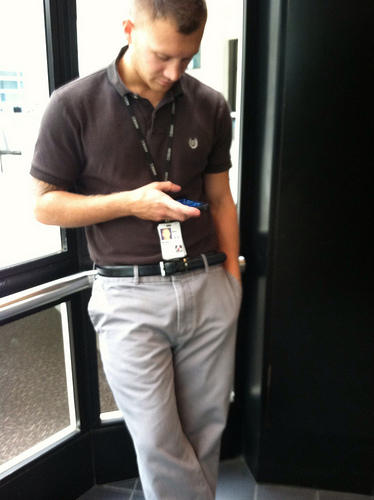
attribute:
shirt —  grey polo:
[26, 43, 233, 266]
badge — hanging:
[123, 95, 187, 259]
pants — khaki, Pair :
[75, 255, 265, 415]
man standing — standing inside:
[30, 0, 292, 497]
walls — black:
[240, 6, 373, 483]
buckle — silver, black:
[160, 254, 194, 273]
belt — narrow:
[95, 248, 229, 275]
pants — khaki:
[92, 248, 286, 483]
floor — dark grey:
[193, 462, 284, 497]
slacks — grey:
[98, 256, 263, 496]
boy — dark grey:
[35, 18, 244, 498]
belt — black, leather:
[95, 251, 226, 275]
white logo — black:
[186, 135, 199, 152]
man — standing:
[32, 0, 241, 498]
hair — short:
[133, 0, 210, 37]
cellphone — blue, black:
[170, 191, 217, 218]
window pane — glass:
[4, 6, 72, 265]